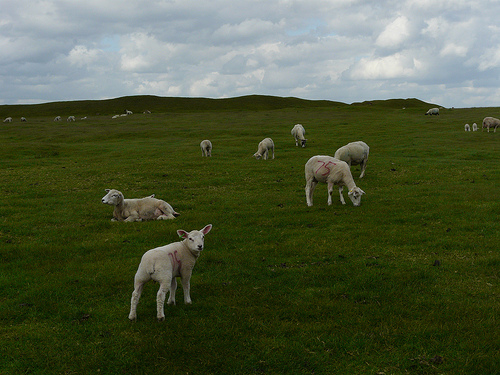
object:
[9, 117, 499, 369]
field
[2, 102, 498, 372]
grass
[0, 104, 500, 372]
ground